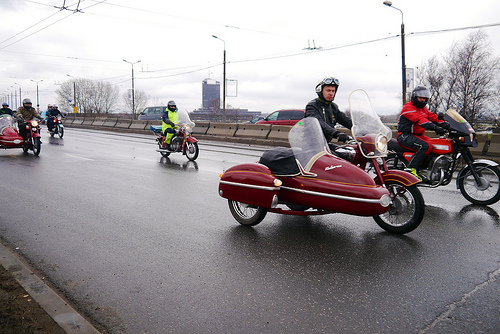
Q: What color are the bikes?
A: Red.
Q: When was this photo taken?
A: During the day.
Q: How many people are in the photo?
A: 6.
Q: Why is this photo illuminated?
A: Sunlight.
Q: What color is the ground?
A: Gray.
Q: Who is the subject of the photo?
A: The people.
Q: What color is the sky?
A: Light Gray.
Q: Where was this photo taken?
A: On a roadway.